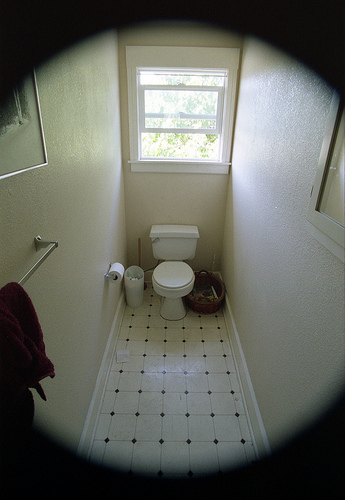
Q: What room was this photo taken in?
A: The bathroom.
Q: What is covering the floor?
A: Tile.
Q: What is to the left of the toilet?
A: A trash can.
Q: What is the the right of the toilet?
A: A basket.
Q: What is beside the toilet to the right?
A: A trash can.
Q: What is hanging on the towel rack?
A: A towel.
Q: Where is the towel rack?
A: On the wall to the right.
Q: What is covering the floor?
A: Linoleum.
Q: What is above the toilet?
A: A window.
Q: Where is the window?
A: Over the toilet.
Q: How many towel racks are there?
A: One.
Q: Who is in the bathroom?
A: No one.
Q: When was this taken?
A: During the day.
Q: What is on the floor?
A: Tile.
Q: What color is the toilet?
A: White.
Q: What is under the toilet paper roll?
A: Trash Can.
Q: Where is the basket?
A: Next to the toilet.